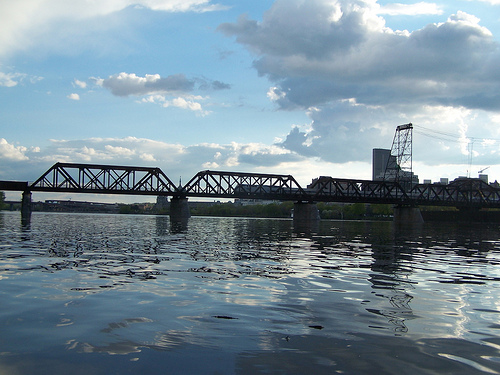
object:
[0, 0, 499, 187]
sky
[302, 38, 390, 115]
cloud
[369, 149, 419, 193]
building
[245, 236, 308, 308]
ripple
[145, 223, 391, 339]
water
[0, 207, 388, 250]
shoreline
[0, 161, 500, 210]
bridge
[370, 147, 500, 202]
city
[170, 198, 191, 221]
base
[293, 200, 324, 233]
braces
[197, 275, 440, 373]
river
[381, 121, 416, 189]
tower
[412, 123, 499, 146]
power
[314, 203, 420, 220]
tree